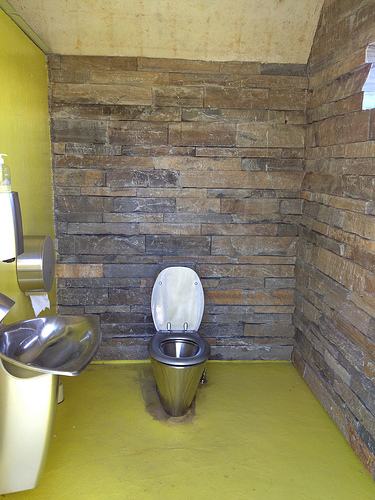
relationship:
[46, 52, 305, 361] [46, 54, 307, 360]
bricks on wall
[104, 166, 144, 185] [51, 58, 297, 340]
brick in wall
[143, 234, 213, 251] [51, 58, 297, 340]
brick in wall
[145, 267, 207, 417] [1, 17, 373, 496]
toilet in bathroom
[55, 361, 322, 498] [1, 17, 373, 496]
green floor in bathroom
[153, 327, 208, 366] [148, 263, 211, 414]
seat on toilet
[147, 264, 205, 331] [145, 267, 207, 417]
lid on toilet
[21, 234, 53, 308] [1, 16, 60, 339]
toilet dispenser on wall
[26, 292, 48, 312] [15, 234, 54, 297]
toilet paper from toilet dispenser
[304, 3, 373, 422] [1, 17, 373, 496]
wall in bathroom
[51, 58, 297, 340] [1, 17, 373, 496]
wall in bathroom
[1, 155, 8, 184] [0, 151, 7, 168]
plastic bottle with pump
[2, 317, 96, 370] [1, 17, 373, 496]
sink in bathroom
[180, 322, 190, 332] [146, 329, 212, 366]
hinge on seat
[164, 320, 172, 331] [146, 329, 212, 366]
hinge on seat